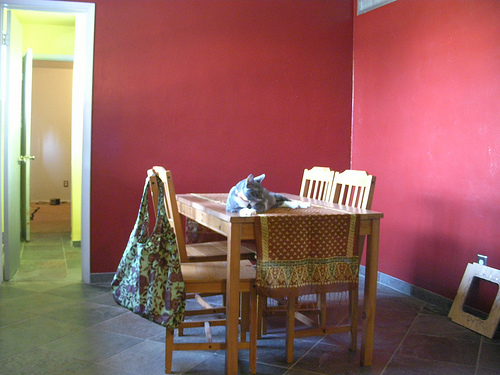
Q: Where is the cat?
A: Table.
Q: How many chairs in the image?
A: Three.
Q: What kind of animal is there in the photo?
A: Cat.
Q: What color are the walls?
A: Red.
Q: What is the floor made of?
A: Tile.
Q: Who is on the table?
A: Cat.